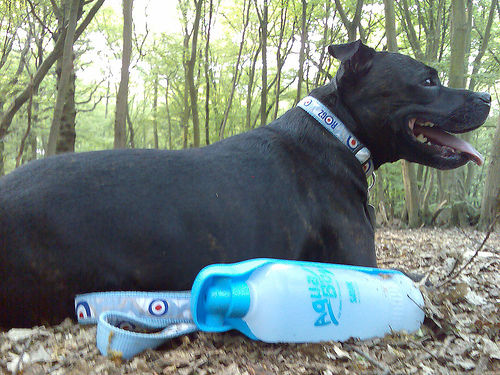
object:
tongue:
[413, 125, 483, 167]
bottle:
[188, 256, 425, 343]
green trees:
[141, 0, 245, 146]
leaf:
[455, 302, 477, 314]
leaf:
[434, 264, 454, 288]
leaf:
[480, 270, 487, 286]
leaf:
[358, 342, 388, 369]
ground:
[455, 240, 499, 373]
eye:
[418, 74, 437, 88]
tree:
[116, 0, 130, 149]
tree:
[49, 2, 84, 154]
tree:
[186, 7, 205, 147]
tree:
[260, 2, 270, 124]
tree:
[292, 0, 308, 105]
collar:
[296, 95, 375, 178]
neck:
[277, 84, 370, 176]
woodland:
[0, 0, 500, 230]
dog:
[0, 39, 493, 331]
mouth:
[398, 106, 484, 170]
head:
[326, 39, 493, 172]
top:
[200, 279, 252, 318]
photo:
[0, 0, 500, 375]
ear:
[327, 39, 377, 78]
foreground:
[0, 177, 500, 375]